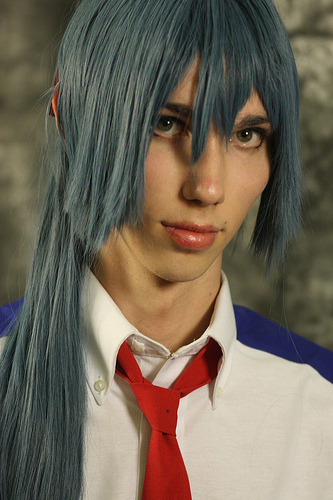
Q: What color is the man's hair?
A: Blue.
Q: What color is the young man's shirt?
A: White with blue shoulders.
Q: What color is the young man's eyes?
A: Brown.